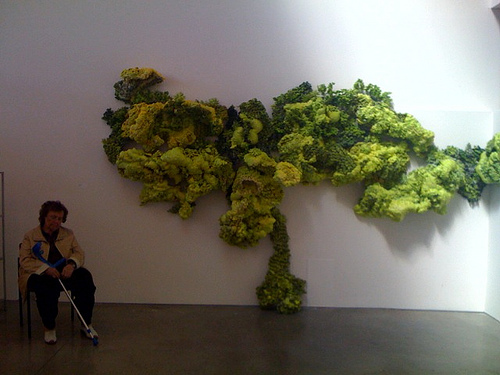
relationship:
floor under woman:
[4, 290, 492, 375] [11, 191, 111, 348]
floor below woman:
[4, 290, 492, 375] [11, 191, 111, 348]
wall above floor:
[2, 4, 500, 301] [4, 290, 492, 375]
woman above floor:
[11, 191, 111, 348] [4, 290, 492, 375]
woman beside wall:
[11, 191, 111, 348] [2, 4, 500, 301]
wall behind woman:
[2, 4, 500, 301] [11, 191, 111, 348]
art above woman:
[105, 67, 494, 311] [11, 191, 111, 348]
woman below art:
[11, 191, 111, 348] [105, 67, 494, 311]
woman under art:
[11, 191, 111, 348] [105, 67, 494, 311]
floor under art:
[4, 290, 492, 375] [105, 67, 494, 311]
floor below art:
[4, 290, 492, 375] [105, 67, 494, 311]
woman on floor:
[11, 191, 111, 348] [4, 290, 492, 375]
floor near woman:
[4, 290, 492, 375] [11, 191, 111, 348]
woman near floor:
[11, 191, 111, 348] [4, 290, 492, 375]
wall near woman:
[2, 4, 500, 301] [11, 191, 111, 348]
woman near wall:
[11, 191, 111, 348] [2, 4, 500, 301]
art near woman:
[105, 67, 494, 311] [11, 191, 111, 348]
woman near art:
[11, 191, 111, 348] [105, 67, 494, 311]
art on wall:
[105, 67, 494, 311] [2, 4, 500, 301]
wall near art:
[2, 4, 500, 301] [105, 67, 494, 311]